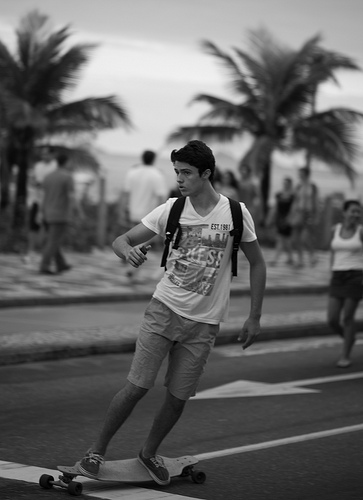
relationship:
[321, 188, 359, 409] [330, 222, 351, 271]
woman wearing shirt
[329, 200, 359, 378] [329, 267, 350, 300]
woman wearing skirt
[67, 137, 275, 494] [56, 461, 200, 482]
boy riding skateboard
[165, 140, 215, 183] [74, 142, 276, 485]
hair on man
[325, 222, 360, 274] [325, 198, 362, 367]
tank top on woman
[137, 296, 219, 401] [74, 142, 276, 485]
shorts on man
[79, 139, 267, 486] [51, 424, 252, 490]
male riding skateboard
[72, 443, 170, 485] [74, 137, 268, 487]
shoes on kid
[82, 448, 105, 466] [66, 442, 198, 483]
shoelace on shoe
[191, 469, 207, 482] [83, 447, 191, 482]
wheel on skateboard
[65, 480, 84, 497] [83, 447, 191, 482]
wheel on skateboard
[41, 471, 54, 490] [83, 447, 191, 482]
wheel on skateboard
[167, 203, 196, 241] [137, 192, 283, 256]
strap on backpack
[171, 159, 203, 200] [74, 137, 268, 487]
facial expression on kid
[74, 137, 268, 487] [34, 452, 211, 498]
kid on skateboard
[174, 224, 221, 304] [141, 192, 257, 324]
design on shirt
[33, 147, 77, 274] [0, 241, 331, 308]
man walking on sidewalk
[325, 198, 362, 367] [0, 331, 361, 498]
woman walking on street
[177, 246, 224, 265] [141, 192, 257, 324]
logo on shirt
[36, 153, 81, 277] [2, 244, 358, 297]
man walking on sidewalk